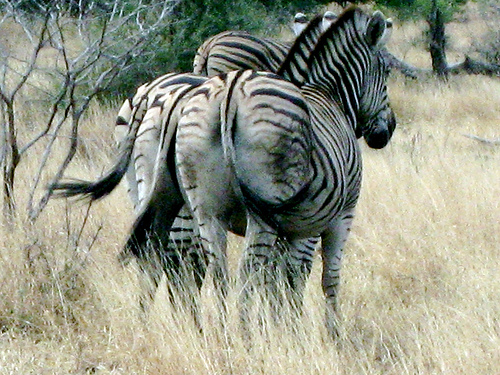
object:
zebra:
[48, 6, 397, 375]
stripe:
[248, 88, 312, 139]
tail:
[215, 83, 314, 241]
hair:
[305, 5, 364, 83]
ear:
[364, 9, 386, 47]